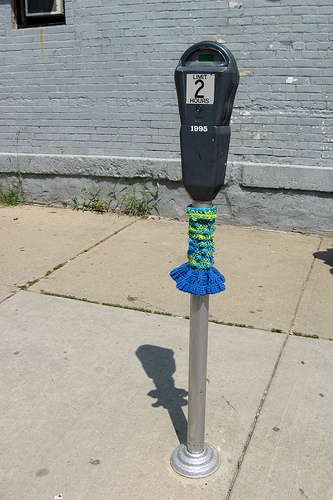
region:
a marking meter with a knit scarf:
[169, 40, 232, 476]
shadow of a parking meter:
[135, 343, 189, 442]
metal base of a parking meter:
[171, 439, 220, 481]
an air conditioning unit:
[22, 0, 65, 17]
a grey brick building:
[0, 0, 332, 231]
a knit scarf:
[168, 205, 225, 296]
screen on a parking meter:
[197, 51, 215, 61]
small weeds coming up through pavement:
[0, 179, 24, 204]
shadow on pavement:
[309, 236, 332, 275]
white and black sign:
[183, 71, 214, 105]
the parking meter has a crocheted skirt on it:
[166, 175, 241, 316]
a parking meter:
[167, 30, 253, 211]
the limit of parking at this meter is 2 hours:
[188, 69, 217, 111]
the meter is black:
[165, 33, 264, 212]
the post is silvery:
[166, 203, 239, 487]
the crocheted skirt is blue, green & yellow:
[163, 195, 249, 318]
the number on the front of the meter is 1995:
[181, 116, 219, 135]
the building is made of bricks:
[101, 16, 155, 117]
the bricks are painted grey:
[98, 3, 147, 102]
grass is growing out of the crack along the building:
[7, 172, 176, 236]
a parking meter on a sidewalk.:
[169, 36, 242, 197]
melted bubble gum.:
[82, 453, 111, 467]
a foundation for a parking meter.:
[169, 442, 225, 475]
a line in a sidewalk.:
[210, 333, 288, 497]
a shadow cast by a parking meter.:
[125, 333, 192, 439]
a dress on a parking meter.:
[164, 202, 230, 306]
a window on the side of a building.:
[5, 0, 72, 29]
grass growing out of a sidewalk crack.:
[0, 163, 161, 220]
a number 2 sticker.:
[174, 68, 216, 117]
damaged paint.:
[278, 69, 300, 90]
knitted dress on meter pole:
[172, 202, 238, 351]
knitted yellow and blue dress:
[166, 203, 227, 303]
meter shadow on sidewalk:
[131, 339, 200, 459]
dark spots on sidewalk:
[27, 454, 126, 494]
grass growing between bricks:
[18, 261, 98, 330]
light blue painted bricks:
[24, 57, 119, 165]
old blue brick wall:
[247, 11, 323, 209]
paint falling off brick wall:
[237, 23, 323, 165]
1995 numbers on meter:
[188, 120, 210, 139]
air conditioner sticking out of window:
[9, 1, 84, 37]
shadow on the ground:
[135, 345, 185, 410]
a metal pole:
[171, 300, 220, 479]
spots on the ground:
[83, 457, 108, 470]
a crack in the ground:
[262, 339, 278, 416]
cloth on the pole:
[186, 210, 216, 277]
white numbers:
[188, 122, 210, 131]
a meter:
[174, 44, 236, 208]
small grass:
[81, 192, 153, 215]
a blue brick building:
[7, 39, 157, 149]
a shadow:
[309, 246, 330, 263]